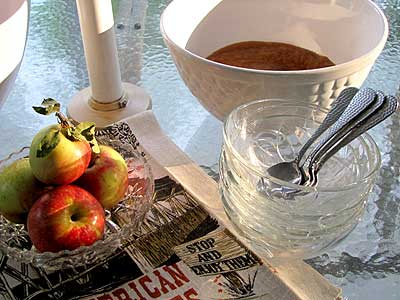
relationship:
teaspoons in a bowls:
[254, 85, 399, 198] [218, 97, 381, 261]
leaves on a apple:
[31, 91, 101, 158] [30, 93, 101, 186]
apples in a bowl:
[9, 97, 131, 253] [0, 145, 156, 270]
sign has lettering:
[171, 228, 263, 294] [185, 236, 255, 276]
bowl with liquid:
[160, 2, 390, 137] [207, 43, 336, 72]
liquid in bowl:
[207, 43, 336, 72] [160, 2, 390, 137]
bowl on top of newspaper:
[0, 145, 156, 270] [3, 110, 341, 299]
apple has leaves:
[30, 93, 101, 186] [31, 91, 101, 158]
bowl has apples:
[0, 145, 156, 270] [9, 97, 131, 253]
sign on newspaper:
[171, 228, 263, 294] [3, 110, 341, 299]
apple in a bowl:
[28, 183, 106, 252] [0, 145, 156, 270]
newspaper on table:
[3, 110, 341, 299] [0, 0, 398, 297]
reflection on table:
[117, 0, 146, 88] [0, 0, 398, 297]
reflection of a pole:
[117, 0, 146, 88] [75, 0, 127, 111]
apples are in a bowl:
[9, 97, 131, 253] [0, 145, 156, 270]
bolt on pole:
[119, 99, 127, 107] [75, 0, 127, 111]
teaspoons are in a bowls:
[254, 85, 399, 198] [218, 97, 381, 261]